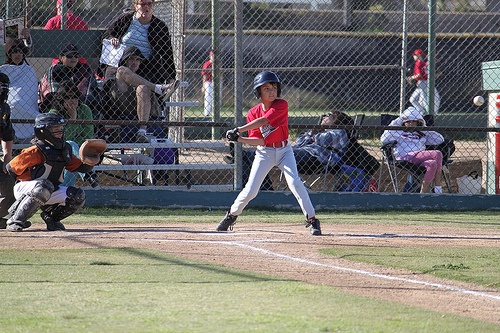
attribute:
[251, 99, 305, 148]
shirt — red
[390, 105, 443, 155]
girl — sitting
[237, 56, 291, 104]
helmet — safety, blue, black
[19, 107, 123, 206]
catcher — behind, kneeling, ready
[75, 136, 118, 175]
glove — brown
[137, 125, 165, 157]
cooler — behind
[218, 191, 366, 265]
cleats — black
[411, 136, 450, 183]
pants — pink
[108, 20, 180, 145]
man — sitting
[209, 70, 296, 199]
boy — playing, swinging, about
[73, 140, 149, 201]
mitt — brown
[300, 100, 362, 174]
woman — reclining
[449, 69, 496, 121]
baseball — airborne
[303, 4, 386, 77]
fence — chain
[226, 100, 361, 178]
jersey — red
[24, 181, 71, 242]
gear — black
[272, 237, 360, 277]
line — white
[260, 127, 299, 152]
belt — red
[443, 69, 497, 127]
ball — white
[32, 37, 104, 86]
people — watching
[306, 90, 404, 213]
lady — sleeping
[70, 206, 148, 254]
plate — home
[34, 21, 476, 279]
field — baseball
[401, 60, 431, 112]
uniform — red, white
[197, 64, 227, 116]
uniform — white, red